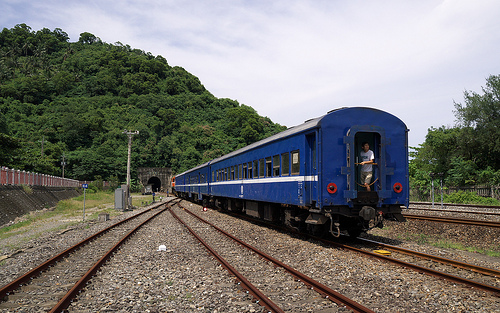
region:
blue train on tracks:
[145, 140, 412, 214]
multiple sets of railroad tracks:
[82, 177, 244, 302]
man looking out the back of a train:
[332, 122, 389, 208]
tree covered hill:
[14, 20, 207, 146]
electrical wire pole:
[107, 104, 152, 223]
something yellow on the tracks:
[365, 235, 399, 263]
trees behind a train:
[411, 90, 493, 194]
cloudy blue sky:
[240, 27, 413, 97]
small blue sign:
[68, 170, 102, 235]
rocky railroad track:
[114, 202, 214, 291]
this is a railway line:
[26, 241, 92, 311]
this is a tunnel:
[148, 167, 165, 189]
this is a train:
[178, 170, 407, 190]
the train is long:
[173, 182, 343, 191]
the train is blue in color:
[253, 145, 277, 154]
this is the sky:
[261, 14, 444, 88]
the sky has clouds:
[256, 28, 339, 83]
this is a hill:
[37, 39, 106, 169]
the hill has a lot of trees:
[23, 35, 86, 155]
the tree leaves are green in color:
[50, 61, 150, 108]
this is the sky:
[185, 11, 478, 65]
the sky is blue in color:
[2, 6, 29, 23]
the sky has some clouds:
[246, 25, 326, 86]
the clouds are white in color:
[317, 20, 378, 88]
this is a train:
[171, 177, 356, 196]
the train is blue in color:
[326, 137, 341, 177]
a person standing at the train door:
[357, 140, 375, 192]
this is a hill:
[18, 35, 80, 163]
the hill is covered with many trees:
[46, 59, 122, 145]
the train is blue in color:
[320, 130, 350, 158]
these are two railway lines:
[56, 227, 258, 301]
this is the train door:
[357, 135, 379, 189]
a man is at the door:
[361, 141, 378, 196]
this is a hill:
[46, 49, 154, 179]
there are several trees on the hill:
[1, 43, 98, 109]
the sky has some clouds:
[166, 6, 286, 44]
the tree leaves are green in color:
[105, 93, 155, 115]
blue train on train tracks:
[171, 103, 410, 236]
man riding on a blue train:
[354, 138, 381, 202]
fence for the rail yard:
[4, 165, 89, 192]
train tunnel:
[139, 169, 169, 196]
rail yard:
[8, 151, 494, 306]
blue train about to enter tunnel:
[170, 106, 412, 241]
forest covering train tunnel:
[10, 21, 255, 194]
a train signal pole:
[117, 127, 142, 183]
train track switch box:
[109, 185, 133, 217]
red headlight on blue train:
[324, 179, 343, 198]